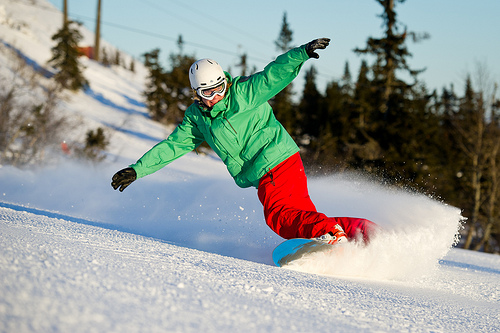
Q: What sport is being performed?
A: Snowboarding.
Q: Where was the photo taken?
A: On a ski slope.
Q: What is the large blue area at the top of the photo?
A: The sky.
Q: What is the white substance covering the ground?
A: Snow.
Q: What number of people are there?
A: One.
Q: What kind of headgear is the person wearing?
A: A helmet.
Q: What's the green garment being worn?
A: A jacket.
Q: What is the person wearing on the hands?
A: Gloves.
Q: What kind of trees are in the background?
A: Pines.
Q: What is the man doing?
A: Snowboarding.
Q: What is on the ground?
A: Snow.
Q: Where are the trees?
A: Behind the snowboarder.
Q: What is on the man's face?
A: Goggles.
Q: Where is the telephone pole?
A: On the snowy hill.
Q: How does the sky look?
A: Clear.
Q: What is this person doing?
A: Snowboarding.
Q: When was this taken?
A: Winter.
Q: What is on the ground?
A: Snow.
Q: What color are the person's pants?
A: Red.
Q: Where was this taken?
A: Ski slope.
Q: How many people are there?
A: 1.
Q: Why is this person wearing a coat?
A: Cold.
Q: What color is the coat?
A: Green.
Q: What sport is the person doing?
A: Snowboarding.